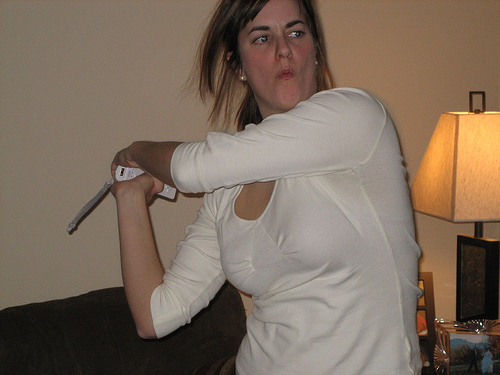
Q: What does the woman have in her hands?
A: Wii Remote.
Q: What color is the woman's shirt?
A: White.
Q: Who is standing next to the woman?
A: No one.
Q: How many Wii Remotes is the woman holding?
A: One.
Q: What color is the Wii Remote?
A: White.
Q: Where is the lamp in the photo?
A: Right.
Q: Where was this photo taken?
A: In a living room.